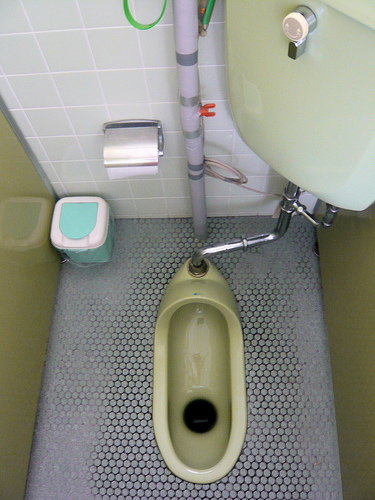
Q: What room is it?
A: It is a bathroom.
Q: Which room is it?
A: It is a bathroom.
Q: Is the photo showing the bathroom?
A: Yes, it is showing the bathroom.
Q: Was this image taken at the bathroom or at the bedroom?
A: It was taken at the bathroom.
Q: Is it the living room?
A: No, it is the bathroom.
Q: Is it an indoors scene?
A: Yes, it is indoors.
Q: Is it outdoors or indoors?
A: It is indoors.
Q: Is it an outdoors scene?
A: No, it is indoors.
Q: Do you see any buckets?
A: No, there are no buckets.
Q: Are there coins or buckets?
A: No, there are no buckets or coins.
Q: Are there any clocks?
A: No, there are no clocks.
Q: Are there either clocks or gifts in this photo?
A: No, there are no clocks or gifts.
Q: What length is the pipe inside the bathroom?
A: The pipe is long.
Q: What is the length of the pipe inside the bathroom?
A: The pipe is long.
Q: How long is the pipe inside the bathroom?
A: The pipe is long.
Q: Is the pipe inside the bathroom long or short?
A: The pipe is long.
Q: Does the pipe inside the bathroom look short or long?
A: The pipe is long.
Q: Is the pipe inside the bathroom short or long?
A: The pipe is long.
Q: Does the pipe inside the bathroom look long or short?
A: The pipe is long.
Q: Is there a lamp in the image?
A: No, there are no lamps.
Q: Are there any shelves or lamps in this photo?
A: No, there are no lamps or shelves.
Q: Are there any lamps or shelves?
A: No, there are no lamps or shelves.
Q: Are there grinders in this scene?
A: No, there are no grinders.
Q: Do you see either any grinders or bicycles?
A: No, there are no grinders or bicycles.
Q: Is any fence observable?
A: No, there are no fences.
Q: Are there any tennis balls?
A: No, there are no tennis balls.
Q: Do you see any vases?
A: No, there are no vases.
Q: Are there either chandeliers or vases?
A: No, there are no vases or chandeliers.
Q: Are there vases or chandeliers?
A: No, there are no vases or chandeliers.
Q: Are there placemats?
A: No, there are no placemats.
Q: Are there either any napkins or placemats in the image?
A: No, there are no placemats or napkins.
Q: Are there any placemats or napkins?
A: No, there are no placemats or napkins.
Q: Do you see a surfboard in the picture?
A: No, there are no surfboards.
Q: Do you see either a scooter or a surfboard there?
A: No, there are no surfboards or scooters.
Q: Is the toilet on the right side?
A: Yes, the toilet is on the right of the image.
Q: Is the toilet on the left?
A: No, the toilet is on the right of the image.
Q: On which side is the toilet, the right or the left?
A: The toilet is on the right of the image.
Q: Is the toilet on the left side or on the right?
A: The toilet is on the right of the image.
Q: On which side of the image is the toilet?
A: The toilet is on the right of the image.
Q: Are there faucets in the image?
A: No, there are no faucets.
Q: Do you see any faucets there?
A: No, there are no faucets.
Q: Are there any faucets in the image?
A: No, there are no faucets.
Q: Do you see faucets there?
A: No, there are no faucets.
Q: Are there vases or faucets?
A: No, there are no faucets or vases.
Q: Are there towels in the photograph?
A: No, there are no towels.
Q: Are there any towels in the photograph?
A: No, there are no towels.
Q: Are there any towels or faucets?
A: No, there are no towels or faucets.